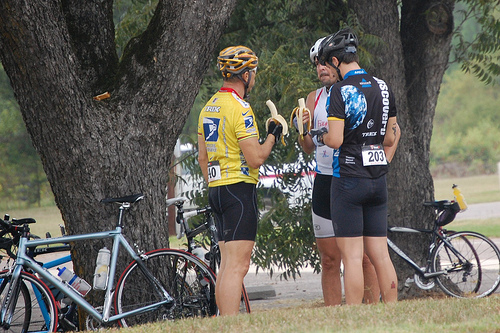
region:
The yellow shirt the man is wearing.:
[197, 91, 260, 183]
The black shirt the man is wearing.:
[325, 70, 394, 155]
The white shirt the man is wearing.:
[309, 84, 340, 175]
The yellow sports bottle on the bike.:
[453, 182, 468, 212]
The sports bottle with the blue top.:
[54, 266, 91, 291]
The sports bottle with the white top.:
[92, 247, 109, 288]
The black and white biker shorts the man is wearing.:
[312, 172, 334, 237]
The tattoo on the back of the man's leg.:
[391, 280, 395, 289]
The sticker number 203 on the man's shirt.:
[362, 144, 386, 165]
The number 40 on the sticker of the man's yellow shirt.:
[204, 165, 218, 178]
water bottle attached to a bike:
[91, 241, 115, 297]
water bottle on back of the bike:
[451, 180, 471, 207]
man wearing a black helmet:
[318, 23, 355, 59]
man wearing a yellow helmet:
[211, 43, 258, 75]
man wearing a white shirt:
[310, 85, 337, 184]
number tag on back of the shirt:
[351, 140, 403, 178]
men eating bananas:
[258, 87, 315, 134]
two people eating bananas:
[185, 23, 351, 323]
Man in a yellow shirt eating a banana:
[195, 44, 290, 317]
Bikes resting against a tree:
[0, 186, 224, 331]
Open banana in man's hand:
[261, 93, 288, 137]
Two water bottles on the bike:
[55, 236, 110, 293]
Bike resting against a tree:
[380, 183, 496, 303]